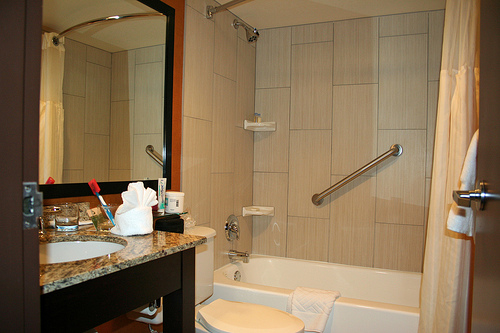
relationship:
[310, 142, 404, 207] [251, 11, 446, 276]
rail bar mounted on shower wall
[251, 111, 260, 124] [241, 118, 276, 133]
bottle sitting on top of shelf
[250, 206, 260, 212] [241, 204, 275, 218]
soap sitting on shelf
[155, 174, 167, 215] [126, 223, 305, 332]
toothpaste above toilet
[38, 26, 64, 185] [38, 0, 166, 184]
shower curtain reflecting in mirror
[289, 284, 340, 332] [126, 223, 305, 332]
towel next to toilet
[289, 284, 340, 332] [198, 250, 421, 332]
towel hanging on bathtub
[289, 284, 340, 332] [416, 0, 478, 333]
towel next to shower curtain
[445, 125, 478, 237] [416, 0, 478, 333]
towel next to shower curtain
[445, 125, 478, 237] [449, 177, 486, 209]
towel next to door handle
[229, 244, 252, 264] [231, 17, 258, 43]
faucet below shower head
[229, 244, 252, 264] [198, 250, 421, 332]
faucet above bathtub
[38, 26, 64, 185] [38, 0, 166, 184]
shower curtain reflected in mirror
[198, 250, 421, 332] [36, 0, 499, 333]
bathtub inside of bathroom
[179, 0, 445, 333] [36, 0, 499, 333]
shower inside of bathroom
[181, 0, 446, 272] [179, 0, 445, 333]
tile inside of shower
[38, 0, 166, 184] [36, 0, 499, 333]
mirror inside of bathroom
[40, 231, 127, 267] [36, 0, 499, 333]
sink inside of bathroom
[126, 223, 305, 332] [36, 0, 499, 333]
toilet inside of bathroom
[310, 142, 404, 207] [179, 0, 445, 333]
rail bar inside of shower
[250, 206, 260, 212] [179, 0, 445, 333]
soap inside of shower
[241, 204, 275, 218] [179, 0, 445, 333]
shelf inside of shower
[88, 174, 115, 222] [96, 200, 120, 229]
toothbrush inside of glass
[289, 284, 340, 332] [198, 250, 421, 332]
towel hanging over bathtub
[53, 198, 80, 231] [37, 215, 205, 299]
glass on top of counter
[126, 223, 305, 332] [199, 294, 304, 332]
toilet has seat